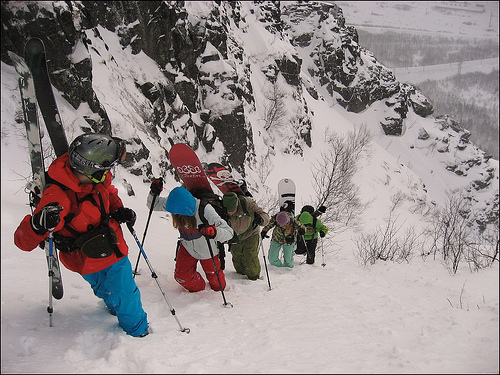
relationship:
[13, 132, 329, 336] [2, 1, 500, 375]
people treking up mountain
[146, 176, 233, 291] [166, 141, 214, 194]
woman carrying snowboard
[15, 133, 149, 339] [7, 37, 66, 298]
person carrying skis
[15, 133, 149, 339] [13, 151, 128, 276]
person in jacket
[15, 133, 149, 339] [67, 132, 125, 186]
person wearing helmet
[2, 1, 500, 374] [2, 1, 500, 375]
snow on side of mountain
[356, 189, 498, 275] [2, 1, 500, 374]
branches sticking out snow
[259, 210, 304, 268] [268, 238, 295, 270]
person dressed in pants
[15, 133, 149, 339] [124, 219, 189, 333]
person holding ski pole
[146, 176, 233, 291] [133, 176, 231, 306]
skier carries ski poles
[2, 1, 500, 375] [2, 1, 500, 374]
mountain covered with snow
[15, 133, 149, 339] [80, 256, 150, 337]
man wearing pants